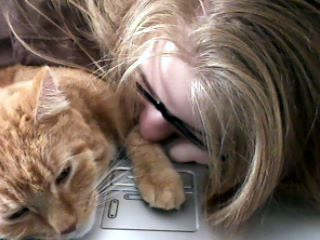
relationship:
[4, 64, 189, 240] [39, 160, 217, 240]
cat on device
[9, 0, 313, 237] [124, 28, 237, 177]
blonde hair on lady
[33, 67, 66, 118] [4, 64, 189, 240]
ear on cat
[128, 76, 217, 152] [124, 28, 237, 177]
glasses on lady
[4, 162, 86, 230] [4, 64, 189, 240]
eyes on cat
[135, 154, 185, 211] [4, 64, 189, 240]
paw on cat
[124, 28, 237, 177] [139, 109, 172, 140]
lady has nose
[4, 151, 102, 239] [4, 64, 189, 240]
face of cat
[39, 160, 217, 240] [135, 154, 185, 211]
device with paw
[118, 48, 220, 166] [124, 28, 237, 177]
face on lady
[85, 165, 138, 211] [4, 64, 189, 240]
whiskers on cat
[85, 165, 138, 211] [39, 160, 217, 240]
whiskers near device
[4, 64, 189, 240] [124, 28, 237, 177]
cat near lady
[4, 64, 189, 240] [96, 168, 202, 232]
cat on device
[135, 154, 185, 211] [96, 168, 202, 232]
paw on device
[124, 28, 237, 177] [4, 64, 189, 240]
lady leaning beside cat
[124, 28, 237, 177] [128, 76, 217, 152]
lady wearing glasses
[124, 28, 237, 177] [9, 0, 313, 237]
lady with blonde hair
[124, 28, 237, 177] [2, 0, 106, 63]
lady wearing brown jacket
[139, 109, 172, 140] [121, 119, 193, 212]
nose against leg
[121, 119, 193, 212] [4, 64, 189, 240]
leg on cat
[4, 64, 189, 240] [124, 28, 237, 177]
cat with lady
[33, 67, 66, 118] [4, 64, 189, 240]
ear of cat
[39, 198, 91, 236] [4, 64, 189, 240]
nose of cat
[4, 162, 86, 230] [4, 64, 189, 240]
eyes of cat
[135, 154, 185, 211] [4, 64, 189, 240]
paw of cat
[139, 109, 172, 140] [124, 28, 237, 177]
nose of lady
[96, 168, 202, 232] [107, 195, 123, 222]
device has button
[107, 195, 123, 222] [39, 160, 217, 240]
button on device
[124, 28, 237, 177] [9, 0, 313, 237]
lady has blonde hair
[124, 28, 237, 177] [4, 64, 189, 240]
lady and cat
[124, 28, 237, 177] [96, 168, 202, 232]
lady on device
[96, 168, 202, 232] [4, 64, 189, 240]
device has cat